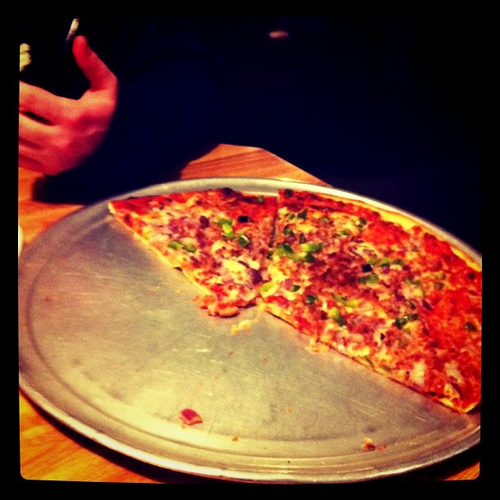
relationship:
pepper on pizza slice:
[167, 238, 196, 255] [101, 188, 275, 318]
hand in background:
[19, 34, 119, 171] [12, 8, 495, 108]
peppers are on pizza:
[155, 201, 411, 333] [112, 187, 479, 411]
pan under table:
[13, 177, 480, 481] [22, 439, 82, 474]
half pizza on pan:
[103, 191, 480, 409] [17, 251, 472, 473]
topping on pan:
[177, 406, 200, 426] [13, 177, 480, 481]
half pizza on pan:
[103, 187, 480, 409] [13, 177, 480, 481]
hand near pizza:
[17, 40, 121, 192] [112, 187, 479, 411]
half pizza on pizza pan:
[103, 187, 480, 409] [20, 100, 480, 485]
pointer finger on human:
[18, 77, 65, 127] [14, 12, 489, 221]